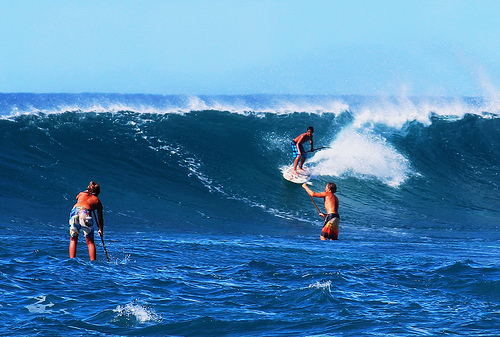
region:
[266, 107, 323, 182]
surfer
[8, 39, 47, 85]
white clouds in blue sky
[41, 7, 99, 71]
white clouds in blue sky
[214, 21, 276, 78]
white clouds in blue sky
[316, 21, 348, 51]
white clouds in blue sky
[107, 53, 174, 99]
white clouds in blue sky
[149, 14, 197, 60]
white clouds in blue sky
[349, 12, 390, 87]
white clouds in blue sky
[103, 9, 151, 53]
white clouds in blue sky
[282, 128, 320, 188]
The guy is surfing a wave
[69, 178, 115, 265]
The man is paddling to the wave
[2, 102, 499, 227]
A big, blue wave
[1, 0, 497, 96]
The sky is blue and clear.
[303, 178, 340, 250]
This guy is wearing black, yellow, and orange swimming trunks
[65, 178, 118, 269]
This guy is wearing blue and white swimming trunks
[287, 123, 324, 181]
This guy is wearing blue swimming trunks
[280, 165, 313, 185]
The surf board is white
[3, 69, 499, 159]
Foam from a wave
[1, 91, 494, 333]
The water is blue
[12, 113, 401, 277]
people in the water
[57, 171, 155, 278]
person on board with paddle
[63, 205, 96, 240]
shorts on the person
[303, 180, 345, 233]
person in the water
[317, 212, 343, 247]
shorts on the person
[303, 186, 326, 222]
paddle in person's hands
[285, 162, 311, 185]
board person stands on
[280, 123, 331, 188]
person on a board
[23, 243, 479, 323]
blue water near people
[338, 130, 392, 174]
splash of white water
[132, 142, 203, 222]
the water is blue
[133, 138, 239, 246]
the water is blue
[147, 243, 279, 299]
the water is blue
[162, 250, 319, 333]
the water is blue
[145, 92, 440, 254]
a big wave of water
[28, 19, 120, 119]
white clouds in blue sky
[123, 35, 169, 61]
white clouds in blue sky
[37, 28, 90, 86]
white clouds in blue sky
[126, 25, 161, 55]
white clouds in blue sky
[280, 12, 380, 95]
white clouds in blue sky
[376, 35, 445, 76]
white clouds in blue sky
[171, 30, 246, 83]
white clouds in blue sky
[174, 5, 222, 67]
white clouds in blue sky